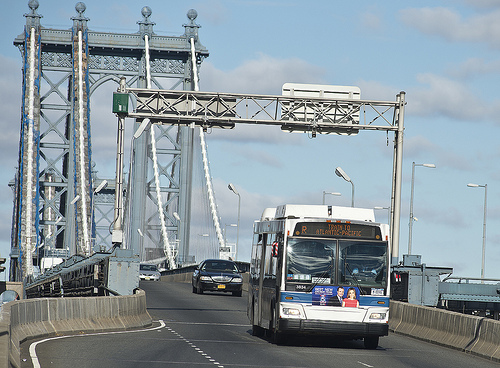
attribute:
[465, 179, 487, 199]
light — street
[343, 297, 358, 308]
top — pink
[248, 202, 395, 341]
bus — blue, white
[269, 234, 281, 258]
mirror — side rear view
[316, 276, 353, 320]
plate — licence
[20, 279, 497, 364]
road — paved, black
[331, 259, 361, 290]
wiper — windshield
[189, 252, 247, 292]
car — black, license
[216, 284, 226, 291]
license plate — orange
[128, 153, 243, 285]
pillars — tall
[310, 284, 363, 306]
sign — advertising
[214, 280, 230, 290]
plate — orange